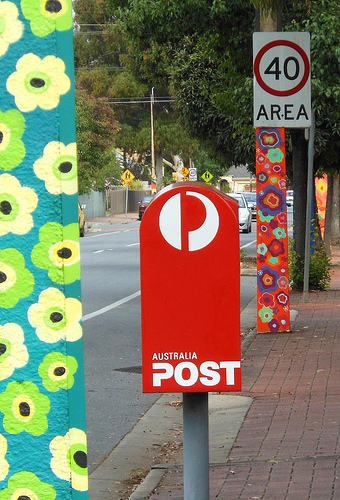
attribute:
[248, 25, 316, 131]
sign — street, white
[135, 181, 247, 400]
sign — red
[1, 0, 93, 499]
post — painted, aqua colored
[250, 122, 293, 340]
post — orange, painted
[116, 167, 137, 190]
street sign — yellow, diamond shaped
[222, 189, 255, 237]
car — white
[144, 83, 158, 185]
pole — electric, light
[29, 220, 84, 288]
flower — colorful, green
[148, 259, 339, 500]
side walk — brick, red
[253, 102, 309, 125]
letters — black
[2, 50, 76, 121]
print — floral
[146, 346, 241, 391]
letters — white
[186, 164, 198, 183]
sign — white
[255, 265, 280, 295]
flower — blue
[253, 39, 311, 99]
circle — red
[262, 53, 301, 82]
number — 40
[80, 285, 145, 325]
paint — white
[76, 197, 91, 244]
vehicle — partially visible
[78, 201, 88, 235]
car — yellow